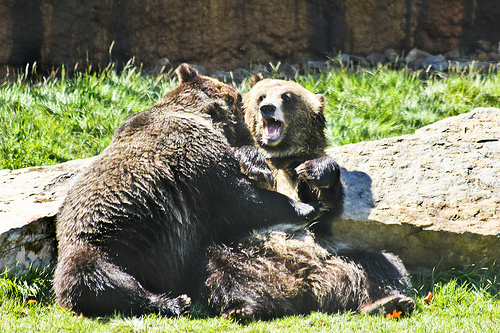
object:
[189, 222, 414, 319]
bear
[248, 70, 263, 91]
ear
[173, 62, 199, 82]
ear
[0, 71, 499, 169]
green grass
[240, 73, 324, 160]
head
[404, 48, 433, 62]
assorted rocks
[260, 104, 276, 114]
nose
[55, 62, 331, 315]
bear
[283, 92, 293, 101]
eye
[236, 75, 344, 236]
bear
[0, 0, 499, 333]
photo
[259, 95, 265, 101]
eye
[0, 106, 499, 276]
rock